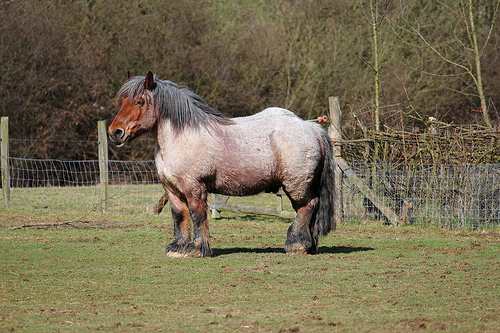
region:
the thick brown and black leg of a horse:
[163, 183, 193, 258]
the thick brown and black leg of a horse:
[178, 172, 210, 257]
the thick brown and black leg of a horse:
[282, 166, 314, 253]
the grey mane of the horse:
[115, 71, 226, 136]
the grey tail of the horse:
[314, 121, 339, 233]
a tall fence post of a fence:
[0, 115, 12, 209]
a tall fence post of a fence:
[94, 118, 111, 208]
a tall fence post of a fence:
[328, 93, 340, 226]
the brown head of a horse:
[105, 78, 155, 145]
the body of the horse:
[157, 108, 323, 253]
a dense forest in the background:
[28, 6, 447, 68]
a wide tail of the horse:
[318, 133, 332, 237]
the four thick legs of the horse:
[164, 183, 323, 252]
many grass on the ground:
[40, 262, 237, 323]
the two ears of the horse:
[126, 69, 154, 89]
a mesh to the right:
[353, 165, 496, 229]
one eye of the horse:
[136, 96, 144, 106]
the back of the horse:
[210, 111, 270, 126]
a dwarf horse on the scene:
[106, 69, 333, 253]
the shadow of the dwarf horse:
[211, 245, 373, 257]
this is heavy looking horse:
[17, 20, 469, 298]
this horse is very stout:
[89, 67, 381, 272]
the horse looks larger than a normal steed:
[103, 65, 350, 274]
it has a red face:
[85, 65, 207, 160]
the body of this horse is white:
[161, 108, 338, 218]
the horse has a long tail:
[301, 130, 363, 245]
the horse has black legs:
[143, 184, 221, 269]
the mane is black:
[148, 70, 227, 132]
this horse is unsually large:
[94, 77, 359, 277]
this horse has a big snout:
[102, 118, 134, 163]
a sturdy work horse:
[110, 73, 340, 255]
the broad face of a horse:
[106, 88, 153, 146]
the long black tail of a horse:
[315, 134, 337, 240]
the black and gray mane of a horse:
[117, 75, 219, 136]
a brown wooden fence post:
[326, 96, 344, 232]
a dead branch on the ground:
[6, 186, 142, 229]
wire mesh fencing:
[337, 161, 498, 232]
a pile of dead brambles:
[339, 109, 498, 223]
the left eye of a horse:
[134, 97, 144, 106]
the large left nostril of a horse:
[112, 126, 124, 138]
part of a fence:
[436, 201, 458, 233]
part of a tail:
[316, 215, 329, 249]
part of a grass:
[331, 260, 340, 276]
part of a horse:
[264, 184, 269, 200]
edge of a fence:
[387, 188, 393, 195]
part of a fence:
[396, 139, 401, 153]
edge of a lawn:
[293, 251, 296, 309]